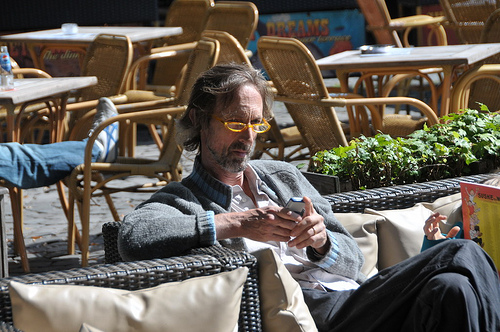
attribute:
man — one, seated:
[164, 63, 363, 314]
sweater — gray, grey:
[114, 152, 363, 288]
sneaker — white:
[82, 98, 126, 172]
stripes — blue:
[94, 116, 118, 153]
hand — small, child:
[416, 202, 472, 245]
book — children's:
[453, 182, 493, 250]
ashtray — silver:
[352, 38, 396, 58]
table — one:
[317, 29, 492, 116]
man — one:
[170, 63, 342, 294]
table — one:
[11, 17, 195, 77]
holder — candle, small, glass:
[50, 14, 89, 39]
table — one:
[6, 51, 101, 142]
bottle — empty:
[0, 38, 15, 92]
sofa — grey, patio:
[88, 154, 492, 295]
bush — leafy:
[317, 86, 492, 185]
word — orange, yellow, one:
[262, 17, 332, 39]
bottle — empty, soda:
[3, 45, 29, 100]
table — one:
[0, 61, 102, 161]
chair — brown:
[64, 41, 220, 243]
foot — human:
[74, 91, 121, 167]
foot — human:
[87, 102, 116, 172]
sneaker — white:
[84, 92, 124, 173]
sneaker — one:
[83, 94, 125, 166]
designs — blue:
[87, 114, 119, 150]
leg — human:
[3, 138, 100, 196]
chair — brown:
[30, 18, 227, 251]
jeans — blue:
[7, 133, 97, 196]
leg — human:
[2, 123, 104, 201]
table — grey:
[5, 61, 107, 168]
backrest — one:
[84, 28, 137, 105]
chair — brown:
[74, 27, 130, 110]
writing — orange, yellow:
[264, 13, 357, 55]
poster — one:
[251, 0, 366, 68]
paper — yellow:
[471, 192, 498, 265]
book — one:
[452, 170, 498, 260]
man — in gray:
[111, 59, 496, 326]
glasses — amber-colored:
[208, 114, 281, 137]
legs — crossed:
[357, 222, 497, 330]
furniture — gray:
[0, 163, 493, 324]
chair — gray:
[2, 245, 266, 330]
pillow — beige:
[9, 270, 249, 328]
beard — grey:
[198, 119, 258, 172]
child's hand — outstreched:
[418, 206, 464, 253]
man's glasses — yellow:
[207, 113, 280, 137]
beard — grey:
[208, 133, 259, 177]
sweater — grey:
[109, 149, 366, 297]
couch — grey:
[100, 171, 495, 319]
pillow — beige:
[325, 210, 394, 270]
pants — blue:
[320, 237, 494, 330]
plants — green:
[317, 110, 493, 196]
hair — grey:
[168, 60, 272, 171]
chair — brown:
[64, 38, 233, 221]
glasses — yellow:
[220, 116, 275, 136]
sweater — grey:
[116, 155, 376, 306]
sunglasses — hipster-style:
[216, 118, 280, 136]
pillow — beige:
[5, 265, 256, 330]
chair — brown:
[255, 32, 441, 155]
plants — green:
[308, 105, 499, 190]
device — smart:
[283, 194, 308, 216]